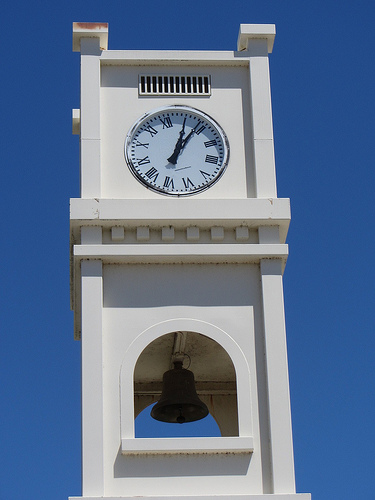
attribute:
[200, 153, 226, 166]
four — roman numeral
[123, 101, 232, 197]
clock — white , tower, metal , big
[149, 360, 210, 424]
bell — big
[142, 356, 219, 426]
bell — large 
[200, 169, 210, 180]
numeral — roman , five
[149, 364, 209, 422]
bell — metallic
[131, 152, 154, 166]
nine — roman numeral 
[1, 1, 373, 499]
sky — blue , clear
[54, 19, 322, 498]
tower — large white , top , clock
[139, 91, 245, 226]
clock — round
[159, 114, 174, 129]
roman numeral — roman 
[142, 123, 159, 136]
roman numeral — roman 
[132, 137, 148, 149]
roman numeral — roman 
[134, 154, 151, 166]
roman numeral — roman 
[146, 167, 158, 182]
roman numeral — roman 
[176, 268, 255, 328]
white tower —  white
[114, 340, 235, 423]
bell — tower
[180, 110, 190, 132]
numeral — roman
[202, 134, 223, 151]
numeral — roman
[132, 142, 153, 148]
numeral — roman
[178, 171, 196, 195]
numeral — roman , six